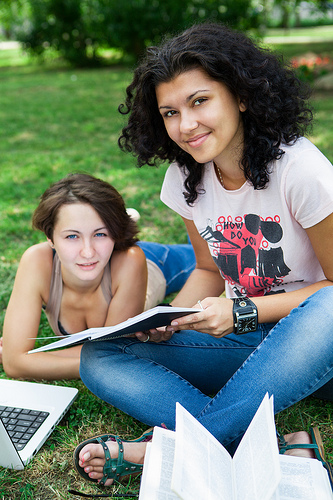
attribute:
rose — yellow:
[300, 50, 330, 78]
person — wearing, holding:
[1, 163, 209, 392]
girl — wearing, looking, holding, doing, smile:
[122, 21, 319, 386]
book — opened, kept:
[49, 265, 199, 408]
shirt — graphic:
[185, 192, 298, 320]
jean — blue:
[71, 338, 206, 459]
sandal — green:
[61, 418, 173, 495]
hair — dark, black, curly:
[261, 60, 304, 140]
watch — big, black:
[221, 286, 277, 341]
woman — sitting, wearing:
[17, 165, 192, 373]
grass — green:
[48, 107, 92, 152]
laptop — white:
[0, 355, 105, 479]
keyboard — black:
[0, 370, 73, 450]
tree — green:
[38, 13, 125, 76]